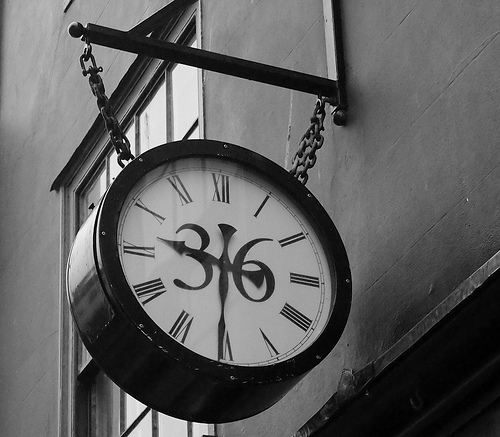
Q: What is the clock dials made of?
A: Metal.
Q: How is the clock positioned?
A: By hanging.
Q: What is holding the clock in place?
A: Chains.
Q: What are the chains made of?
A: Steel.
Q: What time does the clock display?
A: Nine thirty.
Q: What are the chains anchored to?
A: A metal post.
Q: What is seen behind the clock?
A: A window.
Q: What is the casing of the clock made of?
A: Metal.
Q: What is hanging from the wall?
A: A clock.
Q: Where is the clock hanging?
A: On the wall.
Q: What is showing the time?
A: A clock.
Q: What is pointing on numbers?
A: Hands.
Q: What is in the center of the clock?
A: A number.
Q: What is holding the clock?
A: Chain.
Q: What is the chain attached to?
A: A bar.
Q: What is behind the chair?
A: A window.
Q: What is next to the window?
A: A clock.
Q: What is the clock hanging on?
A: Chains.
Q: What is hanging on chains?
A: Clock.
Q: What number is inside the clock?
A: 36.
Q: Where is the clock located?
A: Side of wall.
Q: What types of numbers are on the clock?
A: Roman.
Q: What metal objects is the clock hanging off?
A: Chains.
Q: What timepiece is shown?
A: Clock.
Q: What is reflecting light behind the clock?
A: Window.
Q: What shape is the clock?
A: Round.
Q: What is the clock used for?
A: Time keeping.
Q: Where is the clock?
A: On the building.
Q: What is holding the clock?
A: Chains.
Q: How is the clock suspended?
A: Chains.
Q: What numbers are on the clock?
A: 36.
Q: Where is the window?
A: Behind the clock.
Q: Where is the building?
A: Beside the clock.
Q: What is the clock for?
A: Telling time.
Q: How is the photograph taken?
A: In black and white.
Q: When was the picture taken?
A: 9:31.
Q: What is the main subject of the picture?
A: A clock.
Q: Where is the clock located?
A: Outside a building.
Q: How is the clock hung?
A: By two chains.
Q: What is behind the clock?
A: A window in the building.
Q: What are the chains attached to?
A: A support bar attached to the building.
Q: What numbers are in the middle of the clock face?
A: 36.